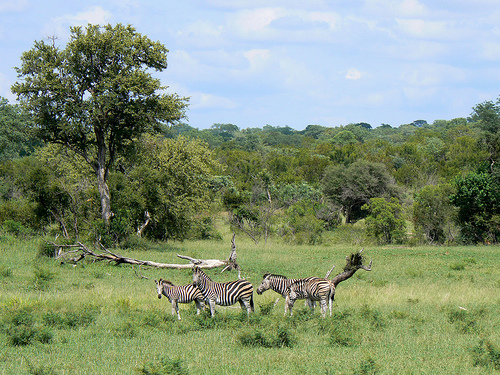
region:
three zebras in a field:
[154, 265, 337, 324]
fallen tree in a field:
[58, 236, 245, 278]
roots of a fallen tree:
[222, 237, 242, 274]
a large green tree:
[20, 25, 177, 247]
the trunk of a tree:
[92, 139, 110, 229]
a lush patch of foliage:
[0, 108, 498, 240]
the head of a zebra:
[153, 277, 164, 298]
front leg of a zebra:
[209, 297, 216, 320]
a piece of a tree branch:
[327, 253, 372, 288]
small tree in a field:
[362, 198, 407, 244]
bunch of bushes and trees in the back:
[2, 105, 496, 235]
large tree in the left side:
[18, 25, 184, 239]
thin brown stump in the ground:
[67, 245, 239, 277]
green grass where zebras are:
[4, 233, 492, 370]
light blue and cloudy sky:
[4, 5, 496, 135]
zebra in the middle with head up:
[192, 266, 255, 319]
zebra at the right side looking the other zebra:
[253, 269, 333, 324]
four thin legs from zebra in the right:
[270, 296, 336, 327]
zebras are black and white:
[154, 267, 335, 323]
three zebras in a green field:
[152, 263, 336, 318]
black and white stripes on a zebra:
[255, 274, 336, 322]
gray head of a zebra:
[153, 274, 165, 301]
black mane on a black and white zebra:
[258, 270, 288, 282]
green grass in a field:
[382, 243, 494, 367]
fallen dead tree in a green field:
[46, 230, 239, 272]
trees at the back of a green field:
[61, 116, 491, 246]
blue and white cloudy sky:
[183, 17, 433, 113]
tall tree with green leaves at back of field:
[5, 16, 187, 251]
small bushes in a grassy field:
[5, 292, 60, 352]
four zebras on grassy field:
[148, 258, 349, 335]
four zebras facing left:
[151, 262, 343, 324]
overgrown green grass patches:
[6, 259, 499, 371]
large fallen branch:
[53, 240, 244, 277]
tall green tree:
[18, 18, 210, 265]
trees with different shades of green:
[0, 99, 497, 239]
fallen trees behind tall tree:
[9, 130, 229, 252]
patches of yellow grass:
[1, 275, 498, 315]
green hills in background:
[11, 102, 499, 154]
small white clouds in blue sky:
[3, 0, 498, 128]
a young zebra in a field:
[152, 279, 208, 319]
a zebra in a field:
[190, 265, 255, 321]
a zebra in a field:
[255, 272, 335, 319]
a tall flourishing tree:
[12, 24, 189, 238]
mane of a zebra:
[263, 273, 285, 280]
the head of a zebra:
[191, 268, 200, 288]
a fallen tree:
[52, 235, 242, 281]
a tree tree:
[449, 172, 499, 242]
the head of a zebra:
[253, 274, 270, 294]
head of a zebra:
[154, 279, 164, 298]